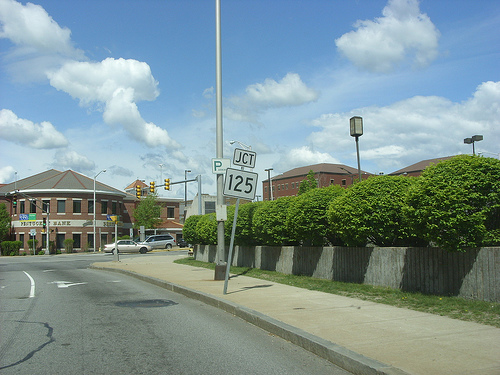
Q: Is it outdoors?
A: Yes, it is outdoors.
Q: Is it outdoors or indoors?
A: It is outdoors.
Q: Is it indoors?
A: No, it is outdoors.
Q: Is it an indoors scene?
A: No, it is outdoors.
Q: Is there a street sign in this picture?
A: Yes, there is a street sign.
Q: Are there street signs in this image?
A: Yes, there is a street sign.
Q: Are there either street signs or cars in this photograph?
A: Yes, there is a street sign.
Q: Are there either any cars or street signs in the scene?
A: Yes, there is a street sign.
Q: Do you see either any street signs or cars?
A: Yes, there is a street sign.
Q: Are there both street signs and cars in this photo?
A: Yes, there are both a street sign and a car.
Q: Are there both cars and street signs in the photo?
A: Yes, there are both a street sign and a car.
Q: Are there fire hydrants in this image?
A: No, there are no fire hydrants.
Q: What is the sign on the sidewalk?
A: The sign is a street sign.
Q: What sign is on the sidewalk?
A: The sign is a street sign.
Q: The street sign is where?
A: The street sign is on the sidewalk.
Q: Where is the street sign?
A: The street sign is on the sidewalk.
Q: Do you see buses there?
A: No, there are no buses.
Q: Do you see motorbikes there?
A: No, there are no motorbikes.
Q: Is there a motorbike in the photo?
A: No, there are no motorcycles.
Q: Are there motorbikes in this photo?
A: No, there are no motorbikes.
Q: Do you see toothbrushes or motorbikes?
A: No, there are no motorbikes or toothbrushes.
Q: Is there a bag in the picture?
A: No, there are no bags.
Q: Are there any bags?
A: No, there are no bags.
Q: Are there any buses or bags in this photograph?
A: No, there are no bags or buses.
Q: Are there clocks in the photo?
A: No, there are no clocks.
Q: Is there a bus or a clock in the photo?
A: No, there are no clocks or buses.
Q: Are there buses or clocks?
A: No, there are no clocks or buses.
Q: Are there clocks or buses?
A: No, there are no clocks or buses.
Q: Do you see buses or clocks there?
A: No, there are no clocks or buses.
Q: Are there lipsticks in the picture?
A: No, there are no lipsticks.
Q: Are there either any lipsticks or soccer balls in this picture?
A: No, there are no lipsticks or soccer balls.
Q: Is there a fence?
A: Yes, there is a fence.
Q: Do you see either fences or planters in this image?
A: Yes, there is a fence.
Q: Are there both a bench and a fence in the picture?
A: No, there is a fence but no benches.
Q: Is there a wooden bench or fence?
A: Yes, there is a wood fence.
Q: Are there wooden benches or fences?
A: Yes, there is a wood fence.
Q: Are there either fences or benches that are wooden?
A: Yes, the fence is wooden.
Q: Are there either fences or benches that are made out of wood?
A: Yes, the fence is made of wood.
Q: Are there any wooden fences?
A: Yes, there is a wood fence.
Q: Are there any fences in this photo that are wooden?
A: Yes, there is a fence that is wooden.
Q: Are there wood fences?
A: Yes, there is a fence that is made of wood.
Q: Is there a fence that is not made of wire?
A: Yes, there is a fence that is made of wood.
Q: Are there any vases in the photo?
A: No, there are no vases.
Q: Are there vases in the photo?
A: No, there are no vases.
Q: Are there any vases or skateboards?
A: No, there are no vases or skateboards.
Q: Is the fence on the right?
A: Yes, the fence is on the right of the image.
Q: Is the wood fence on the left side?
A: No, the fence is on the right of the image.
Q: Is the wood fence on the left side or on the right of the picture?
A: The fence is on the right of the image.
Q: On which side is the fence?
A: The fence is on the right of the image.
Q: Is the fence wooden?
A: Yes, the fence is wooden.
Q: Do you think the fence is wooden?
A: Yes, the fence is wooden.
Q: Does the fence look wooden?
A: Yes, the fence is wooden.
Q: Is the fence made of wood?
A: Yes, the fence is made of wood.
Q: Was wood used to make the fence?
A: Yes, the fence is made of wood.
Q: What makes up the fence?
A: The fence is made of wood.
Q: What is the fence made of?
A: The fence is made of wood.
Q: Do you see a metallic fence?
A: No, there is a fence but it is wooden.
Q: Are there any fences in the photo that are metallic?
A: No, there is a fence but it is wooden.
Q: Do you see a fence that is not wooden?
A: No, there is a fence but it is wooden.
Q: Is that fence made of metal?
A: No, the fence is made of wood.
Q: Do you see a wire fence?
A: No, there is a fence but it is made of wood.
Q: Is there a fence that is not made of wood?
A: No, there is a fence but it is made of wood.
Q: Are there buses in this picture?
A: No, there are no buses.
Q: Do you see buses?
A: No, there are no buses.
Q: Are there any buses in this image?
A: No, there are no buses.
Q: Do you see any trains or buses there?
A: No, there are no buses or trains.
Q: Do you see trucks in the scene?
A: No, there are no trucks.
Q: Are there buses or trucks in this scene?
A: No, there are no trucks or buses.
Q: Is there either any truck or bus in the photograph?
A: No, there are no trucks or buses.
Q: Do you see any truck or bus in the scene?
A: No, there are no trucks or buses.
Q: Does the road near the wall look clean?
A: Yes, the road is clean.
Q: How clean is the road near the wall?
A: The road is clean.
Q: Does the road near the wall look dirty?
A: No, the road is clean.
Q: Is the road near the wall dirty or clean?
A: The road is clean.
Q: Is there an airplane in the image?
A: No, there are no airplanes.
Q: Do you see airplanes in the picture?
A: No, there are no airplanes.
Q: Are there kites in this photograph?
A: No, there are no kites.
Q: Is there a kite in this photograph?
A: No, there are no kites.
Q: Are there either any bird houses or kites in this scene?
A: No, there are no kites or bird houses.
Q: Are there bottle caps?
A: No, there are no bottle caps.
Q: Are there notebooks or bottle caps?
A: No, there are no bottle caps or notebooks.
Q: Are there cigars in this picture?
A: No, there are no cigars.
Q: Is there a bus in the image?
A: No, there are no buses.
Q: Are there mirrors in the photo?
A: No, there are no mirrors.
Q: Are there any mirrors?
A: No, there are no mirrors.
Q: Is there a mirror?
A: No, there are no mirrors.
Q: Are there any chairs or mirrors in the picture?
A: No, there are no mirrors or chairs.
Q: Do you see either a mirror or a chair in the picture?
A: No, there are no mirrors or chairs.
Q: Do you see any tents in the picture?
A: No, there are no tents.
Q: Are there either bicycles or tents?
A: No, there are no tents or bicycles.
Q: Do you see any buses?
A: No, there are no buses.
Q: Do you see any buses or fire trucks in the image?
A: No, there are no buses or fire trucks.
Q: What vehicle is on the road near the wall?
A: The vehicle is a minivan.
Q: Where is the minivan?
A: The minivan is on the road.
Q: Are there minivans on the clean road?
A: Yes, there is a minivan on the road.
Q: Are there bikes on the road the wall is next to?
A: No, there is a minivan on the road.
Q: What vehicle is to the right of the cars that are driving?
A: The vehicle is a minivan.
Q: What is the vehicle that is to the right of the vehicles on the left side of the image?
A: The vehicle is a minivan.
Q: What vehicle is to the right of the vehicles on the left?
A: The vehicle is a minivan.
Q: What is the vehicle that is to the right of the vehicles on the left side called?
A: The vehicle is a minivan.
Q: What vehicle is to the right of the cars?
A: The vehicle is a minivan.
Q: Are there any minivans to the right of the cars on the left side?
A: Yes, there is a minivan to the right of the cars.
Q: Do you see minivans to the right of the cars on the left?
A: Yes, there is a minivan to the right of the cars.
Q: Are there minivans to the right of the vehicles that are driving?
A: Yes, there is a minivan to the right of the cars.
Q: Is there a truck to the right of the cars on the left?
A: No, there is a minivan to the right of the cars.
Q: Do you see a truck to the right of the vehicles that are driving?
A: No, there is a minivan to the right of the cars.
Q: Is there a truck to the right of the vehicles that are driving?
A: No, there is a minivan to the right of the cars.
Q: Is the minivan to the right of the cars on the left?
A: Yes, the minivan is to the right of the cars.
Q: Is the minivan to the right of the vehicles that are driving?
A: Yes, the minivan is to the right of the cars.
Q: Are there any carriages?
A: No, there are no carriages.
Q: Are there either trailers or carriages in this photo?
A: No, there are no carriages or trailers.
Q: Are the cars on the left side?
A: Yes, the cars are on the left of the image.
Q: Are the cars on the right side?
A: No, the cars are on the left of the image.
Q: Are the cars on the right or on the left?
A: The cars are on the left of the image.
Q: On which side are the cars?
A: The cars are on the left of the image.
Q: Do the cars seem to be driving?
A: Yes, the cars are driving.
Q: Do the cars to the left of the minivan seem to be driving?
A: Yes, the cars are driving.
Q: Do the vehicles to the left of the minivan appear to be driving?
A: Yes, the cars are driving.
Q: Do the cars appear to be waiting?
A: No, the cars are driving.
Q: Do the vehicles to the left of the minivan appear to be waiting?
A: No, the cars are driving.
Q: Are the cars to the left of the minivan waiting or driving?
A: The cars are driving.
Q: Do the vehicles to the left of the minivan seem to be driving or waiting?
A: The cars are driving.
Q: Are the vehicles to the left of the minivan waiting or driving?
A: The cars are driving.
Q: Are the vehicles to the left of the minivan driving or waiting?
A: The cars are driving.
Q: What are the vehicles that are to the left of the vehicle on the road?
A: The vehicles are cars.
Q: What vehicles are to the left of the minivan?
A: The vehicles are cars.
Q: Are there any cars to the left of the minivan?
A: Yes, there are cars to the left of the minivan.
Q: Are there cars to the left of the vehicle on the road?
A: Yes, there are cars to the left of the minivan.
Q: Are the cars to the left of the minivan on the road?
A: Yes, the cars are to the left of the minivan.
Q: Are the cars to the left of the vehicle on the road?
A: Yes, the cars are to the left of the minivan.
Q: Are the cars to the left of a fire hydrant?
A: No, the cars are to the left of the minivan.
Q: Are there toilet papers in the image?
A: No, there are no toilet papers.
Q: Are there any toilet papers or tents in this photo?
A: No, there are no toilet papers or tents.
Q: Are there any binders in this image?
A: No, there are no binders.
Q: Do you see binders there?
A: No, there are no binders.